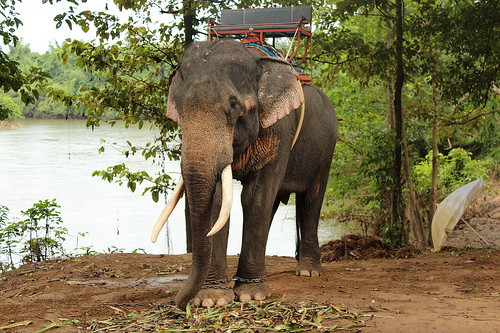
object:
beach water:
[0, 116, 373, 277]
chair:
[203, 3, 317, 69]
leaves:
[7, 300, 378, 333]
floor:
[0, 248, 499, 331]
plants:
[0, 0, 500, 278]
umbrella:
[428, 177, 500, 255]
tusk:
[147, 176, 188, 242]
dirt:
[316, 234, 416, 264]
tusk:
[202, 166, 232, 240]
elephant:
[151, 34, 337, 313]